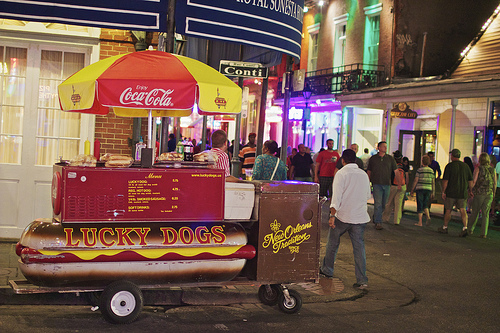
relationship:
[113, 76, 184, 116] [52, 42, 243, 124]
logo on side of umbrella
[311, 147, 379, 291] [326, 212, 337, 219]
man wearing watch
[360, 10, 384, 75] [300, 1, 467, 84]
window on building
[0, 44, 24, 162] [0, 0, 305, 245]
window on building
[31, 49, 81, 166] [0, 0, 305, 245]
window on building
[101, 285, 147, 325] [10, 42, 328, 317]
wheel on cart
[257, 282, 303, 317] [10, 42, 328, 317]
wheel on cart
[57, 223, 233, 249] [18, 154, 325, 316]
writing on cart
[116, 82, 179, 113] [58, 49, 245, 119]
logo on umbrella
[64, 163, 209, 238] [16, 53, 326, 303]
menu on cart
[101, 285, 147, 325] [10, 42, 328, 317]
wheel of a cart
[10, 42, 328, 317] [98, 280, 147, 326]
cart has wheel